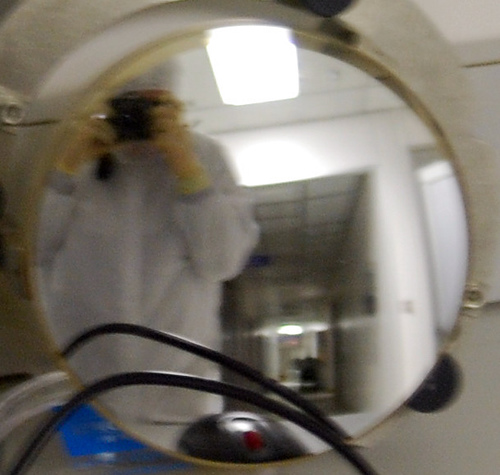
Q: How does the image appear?
A: Blurry.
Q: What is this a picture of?
A: A mirror.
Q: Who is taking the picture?
A: A man in white.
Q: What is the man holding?
A: A camera.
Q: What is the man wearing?
A: A white jacket.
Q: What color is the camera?
A: Black.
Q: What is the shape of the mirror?
A: Round.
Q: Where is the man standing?
A: In a hallway.